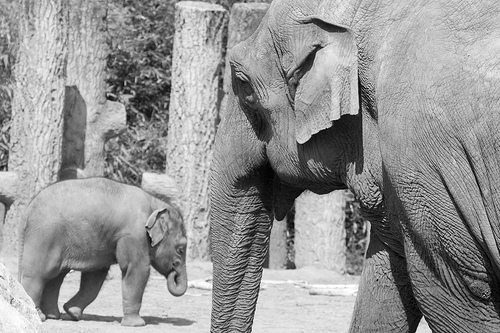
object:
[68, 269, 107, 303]
leg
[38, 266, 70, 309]
leg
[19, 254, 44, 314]
leg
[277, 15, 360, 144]
ear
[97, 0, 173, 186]
forest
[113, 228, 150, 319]
leg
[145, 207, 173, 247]
ear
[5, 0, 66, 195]
tree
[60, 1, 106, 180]
tree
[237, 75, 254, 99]
eye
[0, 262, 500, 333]
ground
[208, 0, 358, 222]
face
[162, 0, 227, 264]
tree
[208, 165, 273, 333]
trunk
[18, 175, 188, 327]
baby elephant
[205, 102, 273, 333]
elephant's trunk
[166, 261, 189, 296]
baby trunk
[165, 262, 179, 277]
mouth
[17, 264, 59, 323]
legs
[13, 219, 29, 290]
tail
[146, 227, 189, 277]
face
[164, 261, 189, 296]
trunk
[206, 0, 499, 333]
elephant